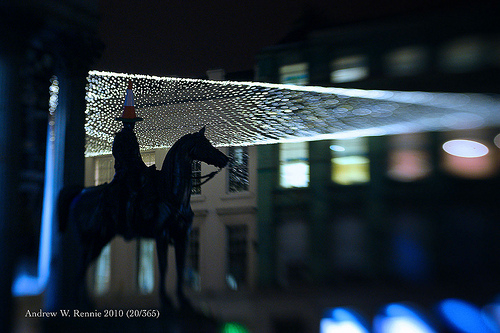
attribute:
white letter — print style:
[83, 309, 91, 319]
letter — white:
[24, 305, 31, 318]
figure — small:
[53, 78, 248, 298]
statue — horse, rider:
[55, 100, 232, 330]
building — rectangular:
[83, 42, 263, 291]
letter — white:
[21, 305, 160, 322]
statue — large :
[58, 102, 239, 304]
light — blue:
[442, 300, 499, 331]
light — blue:
[374, 302, 436, 332]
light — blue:
[321, 308, 371, 331]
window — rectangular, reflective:
[217, 144, 256, 199]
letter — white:
[95, 306, 103, 323]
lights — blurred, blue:
[307, 285, 472, 331]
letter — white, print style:
[70, 307, 79, 319]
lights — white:
[46, 69, 498, 159]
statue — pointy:
[190, 124, 209, 134]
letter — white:
[39, 311, 51, 323]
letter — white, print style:
[88, 310, 92, 315]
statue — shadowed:
[8, 95, 258, 302]